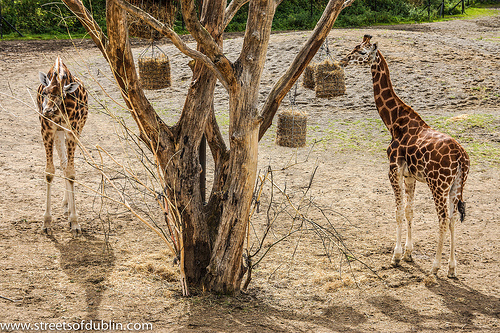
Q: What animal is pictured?
A: Giraffe.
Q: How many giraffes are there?
A: 2.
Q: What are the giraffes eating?
A: Hay.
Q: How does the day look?
A: Sunny.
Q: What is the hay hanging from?
A: A tree.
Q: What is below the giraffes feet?
A: Dirt.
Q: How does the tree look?
A: Bare.